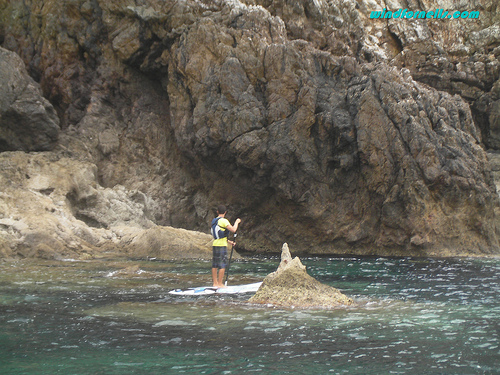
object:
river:
[4, 250, 499, 374]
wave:
[356, 259, 391, 261]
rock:
[246, 241, 354, 308]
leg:
[218, 250, 226, 284]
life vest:
[210, 216, 229, 240]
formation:
[1, 0, 498, 265]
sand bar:
[88, 299, 463, 322]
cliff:
[5, 0, 258, 38]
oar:
[224, 217, 239, 286]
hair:
[217, 204, 226, 214]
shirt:
[211, 218, 231, 247]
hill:
[164, 21, 500, 256]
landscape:
[0, 0, 500, 266]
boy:
[209, 204, 242, 287]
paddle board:
[168, 282, 264, 295]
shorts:
[212, 244, 227, 270]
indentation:
[370, 79, 430, 174]